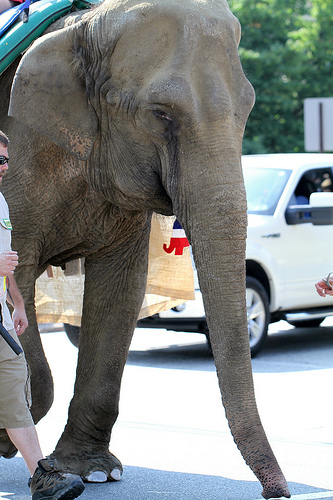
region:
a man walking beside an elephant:
[0, 128, 83, 499]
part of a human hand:
[312, 269, 332, 298]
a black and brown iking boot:
[22, 457, 84, 498]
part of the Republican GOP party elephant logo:
[160, 211, 194, 259]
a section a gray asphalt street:
[138, 335, 205, 499]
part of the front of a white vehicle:
[245, 153, 331, 351]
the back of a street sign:
[301, 93, 331, 151]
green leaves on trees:
[258, 0, 332, 96]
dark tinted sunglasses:
[0, 152, 9, 168]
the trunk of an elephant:
[159, 146, 290, 498]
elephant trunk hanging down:
[162, 117, 280, 498]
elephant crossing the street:
[66, 29, 331, 401]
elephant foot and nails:
[56, 393, 136, 493]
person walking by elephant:
[2, 297, 105, 497]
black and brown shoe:
[20, 457, 88, 498]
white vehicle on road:
[256, 153, 332, 376]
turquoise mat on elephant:
[1, 0, 118, 89]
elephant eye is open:
[126, 77, 217, 144]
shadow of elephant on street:
[39, 433, 315, 497]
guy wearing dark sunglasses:
[1, 130, 20, 204]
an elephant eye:
[152, 105, 174, 124]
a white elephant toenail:
[82, 467, 110, 484]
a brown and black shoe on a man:
[25, 456, 85, 498]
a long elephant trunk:
[163, 143, 295, 499]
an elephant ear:
[11, 13, 100, 170]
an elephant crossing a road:
[0, 1, 293, 499]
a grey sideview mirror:
[290, 190, 332, 221]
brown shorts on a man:
[0, 323, 50, 427]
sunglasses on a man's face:
[0, 152, 15, 167]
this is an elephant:
[29, 0, 246, 441]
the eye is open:
[152, 103, 175, 120]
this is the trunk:
[193, 215, 283, 496]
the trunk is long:
[183, 216, 279, 497]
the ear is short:
[20, 30, 92, 141]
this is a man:
[0, 134, 12, 161]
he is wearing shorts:
[0, 352, 23, 416]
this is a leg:
[62, 242, 160, 477]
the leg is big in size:
[61, 257, 158, 472]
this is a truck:
[266, 161, 310, 279]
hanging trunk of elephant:
[185, 215, 290, 483]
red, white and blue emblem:
[159, 212, 195, 262]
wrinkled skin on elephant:
[98, 137, 136, 191]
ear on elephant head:
[13, 18, 99, 159]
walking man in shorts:
[5, 275, 65, 471]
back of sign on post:
[293, 94, 329, 154]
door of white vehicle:
[283, 225, 326, 291]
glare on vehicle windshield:
[250, 158, 298, 225]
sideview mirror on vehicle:
[293, 187, 328, 228]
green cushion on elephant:
[13, 7, 53, 60]